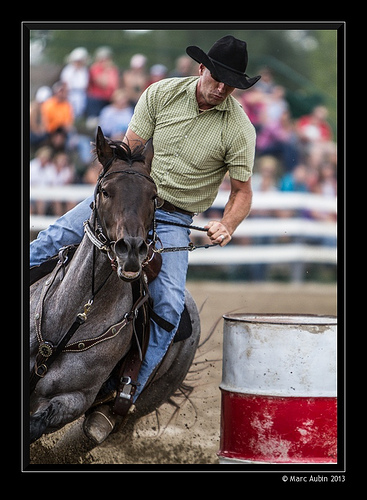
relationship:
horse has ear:
[29, 125, 201, 449] [141, 135, 155, 169]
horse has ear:
[29, 125, 201, 449] [94, 123, 115, 167]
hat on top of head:
[183, 32, 262, 92] [196, 60, 236, 105]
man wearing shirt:
[30, 34, 262, 444] [128, 75, 258, 214]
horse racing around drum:
[29, 125, 201, 449] [220, 308, 337, 463]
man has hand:
[30, 34, 262, 444] [203, 219, 234, 248]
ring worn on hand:
[217, 231, 227, 242] [203, 219, 234, 248]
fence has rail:
[29, 181, 337, 270] [28, 179, 338, 213]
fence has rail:
[29, 181, 337, 270] [28, 213, 336, 240]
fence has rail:
[29, 181, 337, 270] [185, 243, 335, 267]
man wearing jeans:
[30, 34, 262, 444] [29, 190, 194, 406]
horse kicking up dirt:
[29, 125, 201, 449] [19, 319, 221, 464]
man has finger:
[30, 34, 262, 444] [211, 231, 229, 247]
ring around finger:
[217, 231, 227, 242] [211, 231, 229, 247]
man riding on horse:
[30, 34, 262, 444] [29, 125, 201, 449]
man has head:
[30, 34, 262, 444] [196, 60, 236, 105]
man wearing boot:
[30, 34, 262, 444] [80, 393, 120, 444]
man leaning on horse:
[30, 34, 262, 444] [29, 125, 201, 449]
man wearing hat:
[30, 34, 262, 444] [183, 32, 262, 92]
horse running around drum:
[29, 125, 201, 449] [220, 308, 337, 463]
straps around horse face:
[83, 169, 165, 281] [97, 172, 157, 281]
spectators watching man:
[29, 41, 336, 280] [30, 34, 262, 444]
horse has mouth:
[29, 125, 201, 449] [116, 265, 139, 278]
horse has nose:
[29, 125, 201, 449] [114, 234, 151, 276]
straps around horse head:
[83, 169, 165, 281] [90, 124, 160, 283]